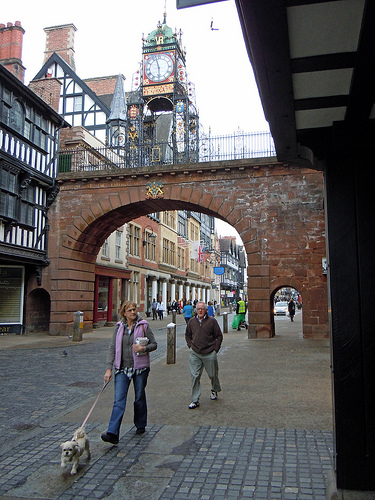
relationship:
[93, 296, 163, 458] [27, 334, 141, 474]
woman on street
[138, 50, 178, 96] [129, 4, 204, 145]
clock on tower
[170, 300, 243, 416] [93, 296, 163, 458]
man near woman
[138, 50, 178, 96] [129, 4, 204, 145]
clock in tower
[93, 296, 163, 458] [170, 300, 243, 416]
woman near man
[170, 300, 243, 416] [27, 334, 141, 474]
man on street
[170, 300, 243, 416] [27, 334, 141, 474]
man in street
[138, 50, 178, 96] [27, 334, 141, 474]
clock in street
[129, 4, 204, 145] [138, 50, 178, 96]
tower has clock